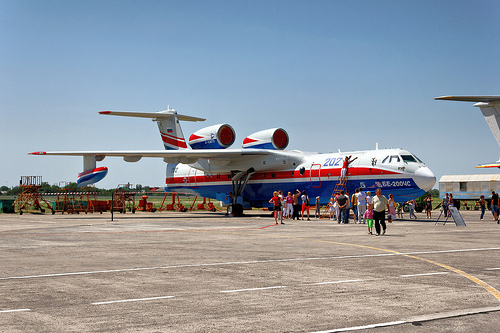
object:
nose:
[412, 165, 437, 192]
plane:
[25, 102, 437, 219]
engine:
[241, 125, 291, 150]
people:
[267, 189, 286, 225]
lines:
[72, 253, 417, 276]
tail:
[430, 92, 498, 149]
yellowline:
[304, 236, 499, 327]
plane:
[431, 87, 499, 171]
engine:
[185, 121, 237, 149]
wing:
[427, 92, 499, 102]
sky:
[46, 16, 446, 66]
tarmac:
[8, 205, 495, 331]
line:
[215, 285, 287, 294]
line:
[313, 275, 370, 287]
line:
[400, 267, 447, 277]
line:
[91, 292, 171, 304]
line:
[0, 306, 30, 315]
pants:
[370, 207, 387, 234]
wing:
[98, 109, 173, 119]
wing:
[176, 113, 205, 123]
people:
[334, 189, 350, 225]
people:
[360, 202, 376, 235]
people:
[283, 190, 298, 221]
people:
[299, 188, 311, 221]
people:
[312, 194, 324, 219]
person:
[289, 188, 304, 221]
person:
[369, 187, 391, 237]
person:
[349, 187, 364, 225]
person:
[279, 196, 290, 221]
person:
[421, 192, 434, 220]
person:
[403, 197, 421, 220]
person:
[223, 190, 238, 214]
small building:
[433, 173, 498, 200]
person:
[353, 185, 372, 225]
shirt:
[270, 195, 284, 206]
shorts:
[270, 203, 284, 212]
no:
[14, 62, 496, 142]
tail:
[95, 102, 209, 134]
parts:
[5, 230, 492, 333]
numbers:
[321, 156, 332, 167]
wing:
[24, 145, 242, 158]